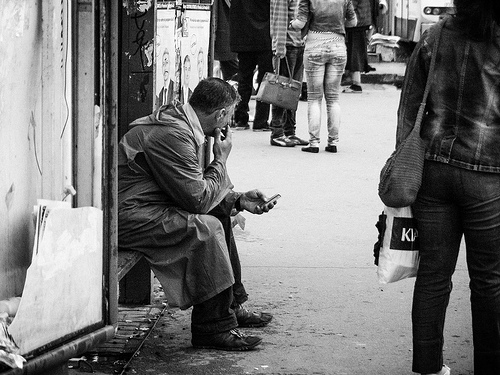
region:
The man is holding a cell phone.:
[249, 182, 282, 216]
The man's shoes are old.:
[187, 300, 282, 355]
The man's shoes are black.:
[185, 302, 280, 354]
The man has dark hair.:
[184, 74, 241, 136]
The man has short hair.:
[189, 73, 250, 131]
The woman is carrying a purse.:
[377, 1, 499, 208]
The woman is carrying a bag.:
[371, 0, 499, 287]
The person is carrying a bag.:
[254, 0, 301, 117]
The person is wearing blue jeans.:
[302, 22, 345, 154]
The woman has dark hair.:
[449, 2, 499, 37]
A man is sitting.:
[118, 77, 279, 354]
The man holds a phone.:
[238, 190, 281, 214]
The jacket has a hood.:
[131, 103, 185, 130]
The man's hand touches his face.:
[210, 116, 235, 164]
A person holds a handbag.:
[252, 44, 302, 112]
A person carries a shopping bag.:
[373, 202, 424, 287]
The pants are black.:
[429, 181, 490, 218]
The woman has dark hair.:
[456, 0, 498, 39]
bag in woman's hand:
[255, 52, 304, 124]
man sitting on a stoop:
[103, 62, 300, 352]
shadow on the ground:
[143, 340, 240, 373]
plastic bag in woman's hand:
[371, 206, 417, 293]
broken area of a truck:
[15, 175, 110, 340]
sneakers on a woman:
[269, 133, 304, 151]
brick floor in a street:
[111, 301, 146, 348]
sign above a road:
[418, 3, 450, 25]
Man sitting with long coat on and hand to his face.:
[118, 73, 283, 353]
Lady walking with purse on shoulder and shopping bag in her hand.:
[376, 0, 498, 374]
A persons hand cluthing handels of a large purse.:
[253, 44, 303, 116]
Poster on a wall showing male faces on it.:
[153, 5, 213, 107]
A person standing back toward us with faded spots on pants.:
[287, 0, 357, 155]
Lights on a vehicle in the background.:
[415, 1, 455, 39]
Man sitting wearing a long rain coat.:
[120, 77, 242, 310]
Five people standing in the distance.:
[210, 2, 385, 154]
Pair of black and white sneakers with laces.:
[267, 131, 310, 149]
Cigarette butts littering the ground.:
[116, 299, 172, 373]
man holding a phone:
[126, 98, 291, 305]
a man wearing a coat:
[163, 115, 268, 285]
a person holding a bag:
[366, 130, 496, 285]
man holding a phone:
[115, 74, 285, 356]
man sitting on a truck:
[120, 73, 281, 358]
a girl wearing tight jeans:
[290, 2, 360, 159]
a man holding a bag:
[253, 7, 309, 150]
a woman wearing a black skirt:
[342, 1, 377, 96]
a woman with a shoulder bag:
[372, 6, 496, 370]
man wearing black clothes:
[227, 2, 272, 136]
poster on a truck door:
[156, 7, 211, 107]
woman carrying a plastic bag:
[369, 6, 497, 369]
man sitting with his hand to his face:
[119, 76, 284, 353]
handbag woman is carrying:
[257, 53, 304, 112]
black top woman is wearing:
[298, 0, 355, 36]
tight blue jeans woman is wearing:
[305, 32, 347, 142]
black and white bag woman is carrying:
[376, 207, 419, 289]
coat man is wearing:
[118, 105, 241, 310]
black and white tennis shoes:
[270, 134, 308, 148]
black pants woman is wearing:
[412, 127, 498, 365]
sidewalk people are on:
[8, 61, 498, 373]